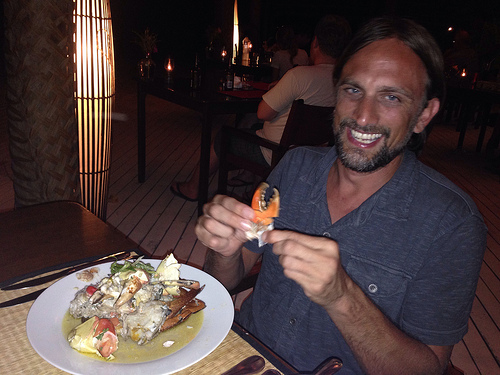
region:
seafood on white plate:
[48, 240, 216, 362]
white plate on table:
[14, 246, 240, 373]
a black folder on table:
[0, 186, 177, 301]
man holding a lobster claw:
[234, 172, 299, 260]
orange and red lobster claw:
[243, 172, 293, 238]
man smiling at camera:
[320, 36, 447, 181]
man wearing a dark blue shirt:
[230, 118, 490, 373]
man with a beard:
[319, 103, 408, 192]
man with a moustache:
[339, 112, 396, 145]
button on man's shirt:
[363, 281, 385, 303]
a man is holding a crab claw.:
[223, 173, 304, 259]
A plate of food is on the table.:
[39, 274, 220, 371]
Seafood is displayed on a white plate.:
[72, 223, 210, 373]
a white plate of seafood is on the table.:
[31, 235, 210, 372]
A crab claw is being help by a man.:
[193, 178, 320, 245]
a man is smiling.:
[323, 110, 414, 178]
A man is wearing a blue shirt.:
[289, 158, 456, 295]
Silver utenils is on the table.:
[226, 348, 336, 373]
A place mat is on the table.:
[1, 265, 23, 367]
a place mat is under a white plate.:
[5, 263, 68, 373]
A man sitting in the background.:
[275, 38, 330, 126]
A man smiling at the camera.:
[334, 39, 422, 194]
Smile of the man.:
[338, 125, 403, 156]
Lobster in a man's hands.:
[242, 182, 294, 247]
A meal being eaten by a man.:
[45, 269, 219, 346]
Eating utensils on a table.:
[12, 268, 44, 300]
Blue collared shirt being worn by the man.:
[377, 202, 470, 289]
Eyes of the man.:
[343, 87, 408, 107]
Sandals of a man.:
[171, 178, 193, 202]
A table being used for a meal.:
[37, 215, 107, 242]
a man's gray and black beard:
[325, 115, 414, 172]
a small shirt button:
[363, 279, 380, 291]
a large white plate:
[26, 255, 237, 373]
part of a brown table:
[0, 198, 297, 373]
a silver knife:
[1, 247, 131, 301]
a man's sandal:
[163, 178, 202, 203]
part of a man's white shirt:
[252, 63, 339, 168]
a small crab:
[249, 183, 287, 226]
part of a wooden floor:
[429, 125, 496, 192]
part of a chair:
[209, 94, 336, 210]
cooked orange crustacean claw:
[246, 180, 282, 235]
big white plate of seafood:
[21, 250, 235, 373]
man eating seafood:
[190, 15, 489, 372]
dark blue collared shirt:
[233, 140, 489, 372]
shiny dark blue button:
[364, 280, 376, 295]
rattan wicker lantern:
[6, 0, 123, 229]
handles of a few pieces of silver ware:
[214, 344, 344, 374]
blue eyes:
[340, 78, 404, 105]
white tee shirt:
[255, 58, 340, 178]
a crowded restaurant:
[0, 2, 495, 372]